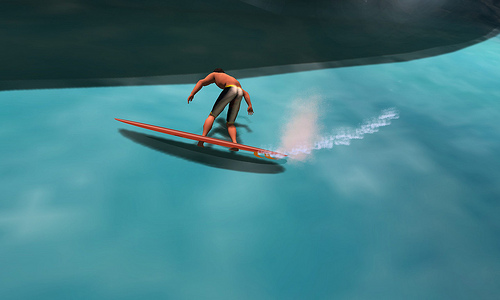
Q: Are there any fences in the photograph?
A: No, there are no fences.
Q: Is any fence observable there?
A: No, there are no fences.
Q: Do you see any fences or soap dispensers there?
A: No, there are no fences or soap dispensers.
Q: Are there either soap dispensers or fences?
A: No, there are no fences or soap dispensers.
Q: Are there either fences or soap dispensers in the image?
A: No, there are no fences or soap dispensers.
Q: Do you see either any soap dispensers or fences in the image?
A: No, there are no fences or soap dispensers.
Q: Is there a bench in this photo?
A: No, there are no benches.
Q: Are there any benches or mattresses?
A: No, there are no benches or mattresses.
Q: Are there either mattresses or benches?
A: No, there are no benches or mattresses.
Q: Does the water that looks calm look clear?
A: No, the water is cloudy.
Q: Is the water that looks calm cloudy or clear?
A: The water is cloudy.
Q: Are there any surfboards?
A: Yes, there is a surfboard.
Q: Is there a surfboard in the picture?
A: Yes, there is a surfboard.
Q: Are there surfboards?
A: Yes, there is a surfboard.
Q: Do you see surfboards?
A: Yes, there is a surfboard.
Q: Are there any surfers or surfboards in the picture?
A: Yes, there is a surfboard.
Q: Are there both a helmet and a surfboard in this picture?
A: No, there is a surfboard but no helmets.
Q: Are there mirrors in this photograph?
A: No, there are no mirrors.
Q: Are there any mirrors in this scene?
A: No, there are no mirrors.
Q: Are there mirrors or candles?
A: No, there are no mirrors or candles.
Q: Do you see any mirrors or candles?
A: No, there are no mirrors or candles.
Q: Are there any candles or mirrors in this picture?
A: No, there are no mirrors or candles.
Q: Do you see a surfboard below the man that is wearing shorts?
A: Yes, there is a surfboard below the man.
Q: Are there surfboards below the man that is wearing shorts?
A: Yes, there is a surfboard below the man.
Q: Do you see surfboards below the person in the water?
A: Yes, there is a surfboard below the man.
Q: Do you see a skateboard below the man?
A: No, there is a surfboard below the man.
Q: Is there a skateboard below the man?
A: No, there is a surfboard below the man.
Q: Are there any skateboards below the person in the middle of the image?
A: No, there is a surfboard below the man.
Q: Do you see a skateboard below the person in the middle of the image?
A: No, there is a surfboard below the man.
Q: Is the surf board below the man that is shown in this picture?
A: Yes, the surf board is below the man.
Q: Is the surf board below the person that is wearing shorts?
A: Yes, the surf board is below the man.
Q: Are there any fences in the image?
A: No, there are no fences.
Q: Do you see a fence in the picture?
A: No, there are no fences.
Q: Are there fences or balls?
A: No, there are no fences or balls.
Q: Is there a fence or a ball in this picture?
A: No, there are no fences or balls.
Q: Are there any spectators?
A: No, there are no spectators.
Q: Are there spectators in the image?
A: No, there are no spectators.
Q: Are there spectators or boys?
A: No, there are no spectators or boys.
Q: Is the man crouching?
A: Yes, the man is crouching.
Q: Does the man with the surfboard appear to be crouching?
A: Yes, the man is crouching.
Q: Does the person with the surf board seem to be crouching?
A: Yes, the man is crouching.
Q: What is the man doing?
A: The man is crouching.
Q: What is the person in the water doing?
A: The man is crouching.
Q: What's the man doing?
A: The man is crouching.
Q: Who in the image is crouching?
A: The man is crouching.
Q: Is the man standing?
A: No, the man is crouching.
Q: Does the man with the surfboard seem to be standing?
A: No, the man is crouching.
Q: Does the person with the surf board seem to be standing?
A: No, the man is crouching.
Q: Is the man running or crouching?
A: The man is crouching.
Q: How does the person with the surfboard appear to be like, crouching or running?
A: The man is crouching.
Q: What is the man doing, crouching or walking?
A: The man is crouching.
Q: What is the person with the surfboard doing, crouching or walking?
A: The man is crouching.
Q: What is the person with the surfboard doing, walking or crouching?
A: The man is crouching.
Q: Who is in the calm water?
A: The man is in the water.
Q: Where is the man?
A: The man is in the water.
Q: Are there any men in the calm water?
A: Yes, there is a man in the water.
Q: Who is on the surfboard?
A: The man is on the surfboard.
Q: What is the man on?
A: The man is on the surfboard.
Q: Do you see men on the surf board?
A: Yes, there is a man on the surf board.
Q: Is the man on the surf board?
A: Yes, the man is on the surf board.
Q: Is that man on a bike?
A: No, the man is on the surf board.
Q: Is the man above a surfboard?
A: Yes, the man is above a surfboard.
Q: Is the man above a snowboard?
A: No, the man is above a surfboard.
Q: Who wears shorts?
A: The man wears shorts.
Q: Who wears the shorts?
A: The man wears shorts.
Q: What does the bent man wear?
A: The man wears shorts.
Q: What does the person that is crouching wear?
A: The man wears shorts.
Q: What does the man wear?
A: The man wears shorts.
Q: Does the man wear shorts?
A: Yes, the man wears shorts.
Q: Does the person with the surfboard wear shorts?
A: Yes, the man wears shorts.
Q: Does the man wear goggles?
A: No, the man wears shorts.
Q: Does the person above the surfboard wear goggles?
A: No, the man wears shorts.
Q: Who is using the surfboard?
A: The man is using the surfboard.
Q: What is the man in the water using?
A: The man is using a surf board.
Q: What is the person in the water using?
A: The man is using a surf board.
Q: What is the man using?
A: The man is using a surf board.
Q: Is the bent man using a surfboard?
A: Yes, the man is using a surfboard.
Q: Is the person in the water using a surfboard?
A: Yes, the man is using a surfboard.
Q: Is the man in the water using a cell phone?
A: No, the man is using a surfboard.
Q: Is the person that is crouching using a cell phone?
A: No, the man is using a surfboard.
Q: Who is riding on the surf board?
A: The man is riding on the surf board.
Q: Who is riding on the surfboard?
A: The man is riding on the surf board.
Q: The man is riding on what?
A: The man is riding on the surfboard.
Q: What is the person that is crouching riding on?
A: The man is riding on the surfboard.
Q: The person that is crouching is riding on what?
A: The man is riding on the surfboard.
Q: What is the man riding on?
A: The man is riding on the surfboard.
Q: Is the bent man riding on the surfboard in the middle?
A: Yes, the man is riding on the surfboard.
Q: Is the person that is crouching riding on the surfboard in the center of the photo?
A: Yes, the man is riding on the surfboard.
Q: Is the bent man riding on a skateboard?
A: No, the man is riding on the surfboard.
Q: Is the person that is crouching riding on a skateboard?
A: No, the man is riding on the surfboard.